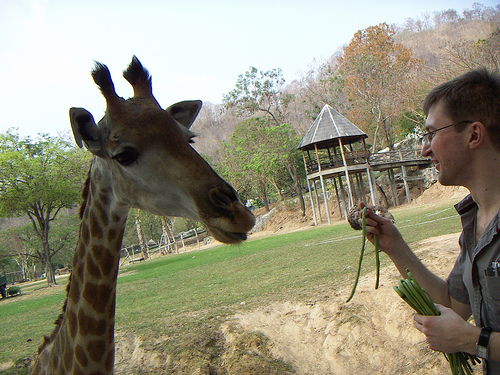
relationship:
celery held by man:
[345, 205, 380, 304] [344, 57, 475, 365]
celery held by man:
[387, 264, 482, 374] [360, 65, 497, 373]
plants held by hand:
[333, 194, 390, 299] [348, 188, 404, 255]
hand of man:
[348, 188, 404, 255] [344, 57, 475, 365]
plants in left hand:
[378, 274, 438, 335] [412, 300, 472, 357]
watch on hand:
[468, 318, 484, 359] [411, 303, 475, 355]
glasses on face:
[410, 120, 483, 154] [421, 105, 453, 187]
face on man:
[421, 105, 453, 187] [344, 57, 484, 351]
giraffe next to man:
[0, 57, 257, 373] [360, 65, 497, 373]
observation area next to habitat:
[300, 86, 384, 250] [3, 125, 482, 373]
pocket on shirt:
[483, 274, 498, 313] [445, 193, 498, 373]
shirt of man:
[445, 193, 498, 373] [360, 65, 497, 373]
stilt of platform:
[318, 175, 331, 227] [301, 101, 398, 231]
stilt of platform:
[299, 173, 318, 223] [301, 101, 398, 231]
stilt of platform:
[311, 179, 324, 221] [301, 101, 398, 231]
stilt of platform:
[345, 171, 359, 215] [301, 101, 398, 231]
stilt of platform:
[363, 163, 379, 209] [301, 101, 398, 231]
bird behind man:
[326, 171, 413, 251] [344, 57, 484, 351]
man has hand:
[344, 57, 484, 351] [356, 204, 396, 254]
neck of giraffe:
[29, 54, 268, 373] [7, 47, 268, 367]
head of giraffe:
[56, 46, 263, 253] [7, 47, 268, 367]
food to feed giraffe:
[392, 272, 477, 372] [7, 47, 268, 367]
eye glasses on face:
[418, 116, 498, 148] [412, 92, 490, 188]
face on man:
[412, 92, 490, 188] [339, 56, 483, 372]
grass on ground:
[0, 196, 499, 373] [4, 160, 477, 344]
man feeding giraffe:
[360, 65, 497, 373] [7, 47, 268, 367]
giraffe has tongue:
[44, 29, 277, 374] [218, 228, 245, 242]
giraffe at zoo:
[7, 47, 268, 367] [5, 58, 484, 372]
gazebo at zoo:
[297, 104, 430, 226] [0, 0, 498, 374]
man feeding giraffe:
[321, 70, 488, 372] [19, 52, 281, 329]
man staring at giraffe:
[360, 65, 497, 373] [27, 53, 257, 373]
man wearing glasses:
[360, 65, 497, 373] [420, 120, 479, 142]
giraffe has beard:
[0, 57, 257, 373] [204, 225, 250, 248]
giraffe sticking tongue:
[27, 53, 257, 373] [223, 229, 250, 239]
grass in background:
[2, 203, 467, 373] [3, 5, 498, 282]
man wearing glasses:
[360, 65, 497, 373] [413, 114, 485, 151]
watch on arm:
[472, 323, 486, 361] [412, 301, 497, 354]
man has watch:
[360, 65, 497, 373] [472, 323, 486, 361]